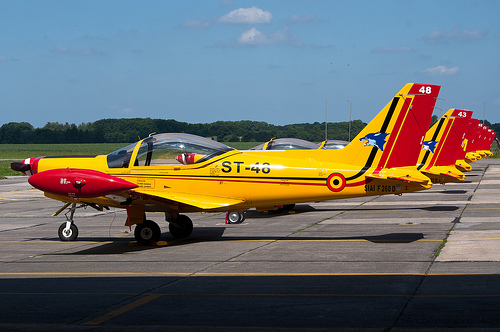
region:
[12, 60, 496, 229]
row of yellow and red airplanes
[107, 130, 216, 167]
cockpit of first airplane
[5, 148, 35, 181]
nose of first plane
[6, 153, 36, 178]
black propellor first plane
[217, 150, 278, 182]
ST-46 on first yellow plane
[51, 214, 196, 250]
black tires of first airplane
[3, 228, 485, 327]
yellow lines on pavement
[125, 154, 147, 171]
steering wheel of first airplane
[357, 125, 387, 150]
animal logo on tail of plane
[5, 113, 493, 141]
trees in the horizon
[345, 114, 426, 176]
Blue wolf logo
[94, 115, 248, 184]
Area where the pilot sits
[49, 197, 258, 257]
Wheels on the plane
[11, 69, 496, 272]
Seven planes lined up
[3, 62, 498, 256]
Row of planes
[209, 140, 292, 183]
ST-48 is on the side of the plane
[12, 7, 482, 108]
Faded clouds in the sky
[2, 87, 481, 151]
Forest lining around the area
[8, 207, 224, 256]
Black and white wheels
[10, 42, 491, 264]
Yellow and red plane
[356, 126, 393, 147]
blue wolf on the tail wing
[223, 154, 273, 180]
black numbers and letters painted on the side of the plane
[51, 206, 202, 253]
landing gear under the plane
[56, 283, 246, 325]
yellow lines painted on the pavement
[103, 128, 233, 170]
cockpit window on top of the plane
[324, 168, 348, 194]
black dot with a yellow and red circle around it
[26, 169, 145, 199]
red engine on the side of the plane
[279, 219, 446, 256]
shadow from plane on the ground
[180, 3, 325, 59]
white clouds in a blue sky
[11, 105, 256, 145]
trees in the distance behind the planes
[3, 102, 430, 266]
yellow and red military jet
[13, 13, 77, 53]
white clouds against blue sky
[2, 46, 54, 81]
white clouds against blue sky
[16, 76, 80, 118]
white clouds against blue sky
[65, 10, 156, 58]
white clouds against blue sky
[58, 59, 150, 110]
white clouds against blue sky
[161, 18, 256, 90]
white clouds against blue sky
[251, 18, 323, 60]
white clouds against blue sky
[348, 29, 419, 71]
white clouds against blue sky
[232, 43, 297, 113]
white clouds against blue sky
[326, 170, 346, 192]
Bulls eye design on plane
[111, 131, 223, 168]
Glass around cockpit is clear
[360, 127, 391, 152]
Wolf logo on tail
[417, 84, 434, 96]
48 printed on tail in white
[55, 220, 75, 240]
Small round black tire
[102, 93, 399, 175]
Black line on plane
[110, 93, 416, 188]
Red line on plane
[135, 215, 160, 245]
Round black tire next to round black tire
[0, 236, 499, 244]
Yellow line underneath plane